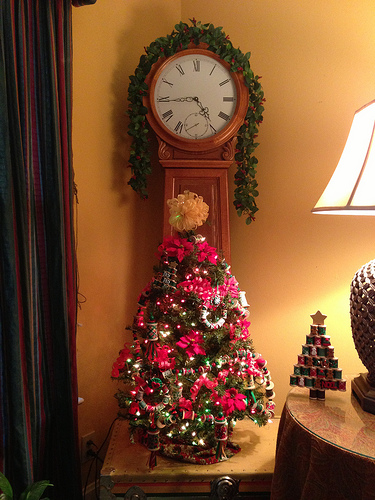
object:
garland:
[127, 15, 266, 226]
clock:
[140, 38, 250, 275]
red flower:
[183, 26, 189, 34]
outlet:
[87, 439, 95, 447]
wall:
[71, 0, 185, 495]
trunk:
[100, 415, 283, 500]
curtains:
[1, 0, 97, 500]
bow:
[166, 190, 209, 234]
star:
[310, 310, 328, 326]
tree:
[289, 310, 347, 401]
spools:
[338, 379, 347, 392]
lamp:
[311, 99, 375, 414]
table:
[286, 372, 375, 499]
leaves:
[0, 472, 51, 500]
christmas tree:
[110, 190, 276, 470]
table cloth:
[270, 373, 374, 500]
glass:
[287, 373, 375, 461]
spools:
[289, 374, 298, 388]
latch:
[208, 474, 241, 499]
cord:
[84, 415, 120, 499]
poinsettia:
[154, 234, 197, 263]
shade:
[311, 99, 375, 217]